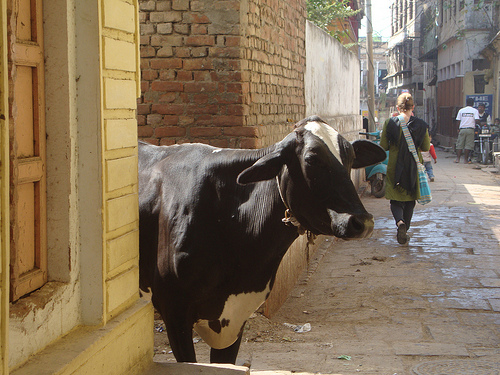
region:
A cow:
[139, 144, 384, 259]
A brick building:
[159, 15, 311, 125]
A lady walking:
[378, 93, 456, 243]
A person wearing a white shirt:
[450, 95, 484, 132]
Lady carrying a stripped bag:
[413, 163, 440, 206]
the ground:
[386, 236, 494, 327]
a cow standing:
[183, 151, 354, 277]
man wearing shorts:
[451, 128, 485, 151]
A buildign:
[395, 21, 497, 78]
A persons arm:
[430, 145, 447, 163]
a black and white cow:
[119, 113, 387, 370]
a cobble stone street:
[274, 153, 496, 365]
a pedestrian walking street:
[380, 89, 430, 241]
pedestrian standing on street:
[452, 96, 482, 162]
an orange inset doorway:
[8, 0, 65, 302]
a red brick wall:
[142, 1, 305, 158]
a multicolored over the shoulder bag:
[391, 110, 433, 208]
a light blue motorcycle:
[360, 127, 388, 198]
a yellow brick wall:
[94, 6, 142, 307]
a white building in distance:
[385, 0, 432, 138]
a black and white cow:
[200, 80, 360, 315]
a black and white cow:
[186, 194, 364, 368]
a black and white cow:
[258, 122, 410, 302]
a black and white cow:
[218, 110, 315, 352]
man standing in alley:
[450, 90, 482, 167]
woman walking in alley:
[376, 90, 431, 250]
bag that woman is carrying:
[394, 106, 442, 226]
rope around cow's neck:
[267, 154, 294, 256]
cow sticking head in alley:
[234, 108, 381, 301]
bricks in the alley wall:
[221, 93, 295, 140]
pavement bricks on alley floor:
[411, 227, 493, 347]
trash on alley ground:
[264, 292, 326, 361]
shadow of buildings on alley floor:
[445, 171, 489, 220]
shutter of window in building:
[16, 91, 58, 304]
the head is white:
[233, 80, 410, 238]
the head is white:
[287, 132, 428, 302]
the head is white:
[259, 81, 370, 182]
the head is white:
[280, 65, 384, 369]